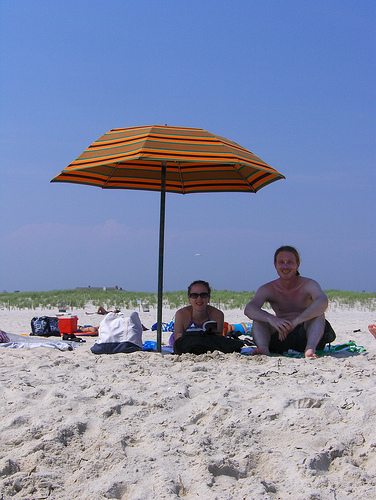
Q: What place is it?
A: It is a beach.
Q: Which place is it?
A: It is a beach.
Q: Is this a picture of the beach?
A: Yes, it is showing the beach.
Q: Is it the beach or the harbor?
A: It is the beach.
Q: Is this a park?
A: No, it is a beach.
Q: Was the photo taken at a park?
A: No, the picture was taken in a beach.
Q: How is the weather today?
A: It is clear.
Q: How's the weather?
A: It is clear.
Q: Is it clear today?
A: Yes, it is clear.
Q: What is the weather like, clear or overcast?
A: It is clear.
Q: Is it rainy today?
A: No, it is clear.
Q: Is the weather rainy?
A: No, it is clear.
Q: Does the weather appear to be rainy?
A: No, it is clear.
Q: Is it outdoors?
A: Yes, it is outdoors.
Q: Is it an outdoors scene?
A: Yes, it is outdoors.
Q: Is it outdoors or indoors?
A: It is outdoors.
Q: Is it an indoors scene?
A: No, it is outdoors.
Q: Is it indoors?
A: No, it is outdoors.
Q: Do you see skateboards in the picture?
A: No, there are no skateboards.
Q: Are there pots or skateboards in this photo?
A: No, there are no skateboards or pots.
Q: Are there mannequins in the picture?
A: No, there are no mannequins.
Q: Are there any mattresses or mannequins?
A: No, there are no mannequins or mattresses.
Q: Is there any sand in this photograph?
A: Yes, there is sand.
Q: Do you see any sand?
A: Yes, there is sand.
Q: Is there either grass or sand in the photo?
A: Yes, there is sand.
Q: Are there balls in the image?
A: No, there are no balls.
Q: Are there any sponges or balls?
A: No, there are no balls or sponges.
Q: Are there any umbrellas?
A: Yes, there is an umbrella.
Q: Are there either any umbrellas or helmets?
A: Yes, there is an umbrella.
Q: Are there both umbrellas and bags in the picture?
A: Yes, there are both an umbrella and a bag.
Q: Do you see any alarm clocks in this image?
A: No, there are no alarm clocks.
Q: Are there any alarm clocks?
A: No, there are no alarm clocks.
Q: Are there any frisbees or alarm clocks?
A: No, there are no alarm clocks or frisbees.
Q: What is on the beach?
A: The umbrella is on the beach.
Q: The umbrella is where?
A: The umbrella is on the beach.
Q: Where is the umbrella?
A: The umbrella is on the beach.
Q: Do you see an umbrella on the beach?
A: Yes, there is an umbrella on the beach.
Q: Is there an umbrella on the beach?
A: Yes, there is an umbrella on the beach.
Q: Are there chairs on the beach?
A: No, there is an umbrella on the beach.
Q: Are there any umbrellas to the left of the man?
A: Yes, there is an umbrella to the left of the man.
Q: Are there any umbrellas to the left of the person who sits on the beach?
A: Yes, there is an umbrella to the left of the man.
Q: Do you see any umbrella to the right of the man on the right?
A: No, the umbrella is to the left of the man.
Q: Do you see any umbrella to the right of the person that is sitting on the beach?
A: No, the umbrella is to the left of the man.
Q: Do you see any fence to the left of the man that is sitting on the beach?
A: No, there is an umbrella to the left of the man.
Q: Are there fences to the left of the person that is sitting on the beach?
A: No, there is an umbrella to the left of the man.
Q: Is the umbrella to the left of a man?
A: Yes, the umbrella is to the left of a man.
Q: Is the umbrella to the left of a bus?
A: No, the umbrella is to the left of a man.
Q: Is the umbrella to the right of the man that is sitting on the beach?
A: No, the umbrella is to the left of the man.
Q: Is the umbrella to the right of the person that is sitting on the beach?
A: No, the umbrella is to the left of the man.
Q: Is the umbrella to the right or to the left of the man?
A: The umbrella is to the left of the man.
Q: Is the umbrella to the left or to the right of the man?
A: The umbrella is to the left of the man.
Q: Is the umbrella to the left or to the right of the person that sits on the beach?
A: The umbrella is to the left of the man.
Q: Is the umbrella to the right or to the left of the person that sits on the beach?
A: The umbrella is to the left of the man.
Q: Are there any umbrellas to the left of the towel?
A: Yes, there is an umbrella to the left of the towel.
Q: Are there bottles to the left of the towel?
A: No, there is an umbrella to the left of the towel.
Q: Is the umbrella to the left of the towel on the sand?
A: Yes, the umbrella is to the left of the towel.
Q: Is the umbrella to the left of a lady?
A: No, the umbrella is to the left of the towel.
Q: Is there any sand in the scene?
A: Yes, there is sand.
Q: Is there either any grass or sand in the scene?
A: Yes, there is sand.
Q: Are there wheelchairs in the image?
A: No, there are no wheelchairs.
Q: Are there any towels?
A: Yes, there is a towel.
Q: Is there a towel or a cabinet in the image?
A: Yes, there is a towel.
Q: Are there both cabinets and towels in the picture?
A: No, there is a towel but no cabinets.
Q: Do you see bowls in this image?
A: No, there are no bowls.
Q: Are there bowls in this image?
A: No, there are no bowls.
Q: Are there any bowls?
A: No, there are no bowls.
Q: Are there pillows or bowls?
A: No, there are no bowls or pillows.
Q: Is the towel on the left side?
A: No, the towel is on the right of the image.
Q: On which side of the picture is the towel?
A: The towel is on the right of the image.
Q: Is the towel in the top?
A: No, the towel is in the bottom of the image.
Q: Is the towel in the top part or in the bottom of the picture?
A: The towel is in the bottom of the image.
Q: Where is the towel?
A: The towel is on the sand.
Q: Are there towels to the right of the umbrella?
A: Yes, there is a towel to the right of the umbrella.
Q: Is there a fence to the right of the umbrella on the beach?
A: No, there is a towel to the right of the umbrella.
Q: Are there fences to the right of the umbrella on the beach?
A: No, there is a towel to the right of the umbrella.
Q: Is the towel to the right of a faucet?
A: No, the towel is to the right of the umbrella.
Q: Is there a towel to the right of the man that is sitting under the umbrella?
A: Yes, there is a towel to the right of the man.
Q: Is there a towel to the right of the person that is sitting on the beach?
A: Yes, there is a towel to the right of the man.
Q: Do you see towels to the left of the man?
A: No, the towel is to the right of the man.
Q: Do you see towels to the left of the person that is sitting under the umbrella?
A: No, the towel is to the right of the man.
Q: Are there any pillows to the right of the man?
A: No, there is a towel to the right of the man.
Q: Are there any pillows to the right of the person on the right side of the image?
A: No, there is a towel to the right of the man.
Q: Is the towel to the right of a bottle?
A: No, the towel is to the right of the man.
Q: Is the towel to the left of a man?
A: No, the towel is to the right of a man.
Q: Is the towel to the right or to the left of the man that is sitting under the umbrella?
A: The towel is to the right of the man.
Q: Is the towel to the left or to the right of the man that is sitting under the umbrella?
A: The towel is to the right of the man.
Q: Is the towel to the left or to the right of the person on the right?
A: The towel is to the right of the man.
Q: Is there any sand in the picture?
A: Yes, there is sand.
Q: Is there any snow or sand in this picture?
A: Yes, there is sand.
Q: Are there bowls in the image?
A: No, there are no bowls.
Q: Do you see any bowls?
A: No, there are no bowls.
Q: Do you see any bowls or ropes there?
A: No, there are no bowls or ropes.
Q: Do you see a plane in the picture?
A: No, there are no airplanes.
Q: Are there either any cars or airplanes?
A: No, there are no airplanes or cars.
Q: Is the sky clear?
A: Yes, the sky is clear.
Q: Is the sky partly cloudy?
A: No, the sky is clear.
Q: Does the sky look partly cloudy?
A: No, the sky is clear.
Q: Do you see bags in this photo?
A: Yes, there is a bag.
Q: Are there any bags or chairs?
A: Yes, there is a bag.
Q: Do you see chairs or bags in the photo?
A: Yes, there is a bag.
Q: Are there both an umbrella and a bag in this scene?
A: Yes, there are both a bag and an umbrella.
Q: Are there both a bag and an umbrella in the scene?
A: Yes, there are both a bag and an umbrella.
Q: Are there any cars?
A: No, there are no cars.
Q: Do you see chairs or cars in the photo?
A: No, there are no cars or chairs.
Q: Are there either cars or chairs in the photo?
A: No, there are no cars or chairs.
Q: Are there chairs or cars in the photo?
A: No, there are no cars or chairs.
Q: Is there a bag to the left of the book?
A: Yes, there is a bag to the left of the book.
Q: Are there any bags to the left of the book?
A: Yes, there is a bag to the left of the book.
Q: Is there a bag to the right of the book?
A: No, the bag is to the left of the book.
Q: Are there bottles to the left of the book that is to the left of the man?
A: No, there is a bag to the left of the book.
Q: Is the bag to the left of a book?
A: Yes, the bag is to the left of a book.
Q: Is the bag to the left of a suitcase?
A: No, the bag is to the left of a book.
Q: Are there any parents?
A: No, there are no parents.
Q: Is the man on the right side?
A: Yes, the man is on the right of the image.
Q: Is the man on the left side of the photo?
A: No, the man is on the right of the image.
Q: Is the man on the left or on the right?
A: The man is on the right of the image.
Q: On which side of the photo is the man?
A: The man is on the right of the image.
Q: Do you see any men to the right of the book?
A: Yes, there is a man to the right of the book.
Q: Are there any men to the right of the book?
A: Yes, there is a man to the right of the book.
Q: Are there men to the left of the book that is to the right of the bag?
A: No, the man is to the right of the book.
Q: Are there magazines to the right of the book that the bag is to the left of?
A: No, there is a man to the right of the book.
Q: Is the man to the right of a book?
A: Yes, the man is to the right of a book.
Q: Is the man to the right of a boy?
A: No, the man is to the right of a book.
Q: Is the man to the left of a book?
A: No, the man is to the right of a book.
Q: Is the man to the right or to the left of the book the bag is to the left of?
A: The man is to the right of the book.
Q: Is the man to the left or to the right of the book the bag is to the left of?
A: The man is to the right of the book.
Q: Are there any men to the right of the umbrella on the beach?
A: Yes, there is a man to the right of the umbrella.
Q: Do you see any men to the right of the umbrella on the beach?
A: Yes, there is a man to the right of the umbrella.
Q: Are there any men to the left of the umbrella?
A: No, the man is to the right of the umbrella.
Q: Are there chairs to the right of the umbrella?
A: No, there is a man to the right of the umbrella.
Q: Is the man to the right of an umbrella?
A: Yes, the man is to the right of an umbrella.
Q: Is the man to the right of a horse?
A: No, the man is to the right of an umbrella.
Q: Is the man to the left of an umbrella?
A: No, the man is to the right of an umbrella.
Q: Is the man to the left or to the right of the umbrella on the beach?
A: The man is to the right of the umbrella.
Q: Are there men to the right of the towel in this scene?
A: No, the man is to the left of the towel.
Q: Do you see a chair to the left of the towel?
A: No, there is a man to the left of the towel.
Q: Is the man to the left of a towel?
A: Yes, the man is to the left of a towel.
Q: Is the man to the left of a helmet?
A: No, the man is to the left of a towel.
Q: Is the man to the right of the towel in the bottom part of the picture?
A: No, the man is to the left of the towel.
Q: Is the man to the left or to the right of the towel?
A: The man is to the left of the towel.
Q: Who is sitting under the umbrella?
A: The man is sitting under the umbrella.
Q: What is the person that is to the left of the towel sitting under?
A: The man is sitting under the umbrella.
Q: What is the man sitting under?
A: The man is sitting under the umbrella.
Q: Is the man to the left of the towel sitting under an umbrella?
A: Yes, the man is sitting under an umbrella.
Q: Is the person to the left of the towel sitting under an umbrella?
A: Yes, the man is sitting under an umbrella.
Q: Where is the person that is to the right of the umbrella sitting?
A: The man is sitting on the beach.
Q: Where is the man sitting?
A: The man is sitting on the beach.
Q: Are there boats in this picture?
A: No, there are no boats.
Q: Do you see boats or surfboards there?
A: No, there are no boats or surfboards.